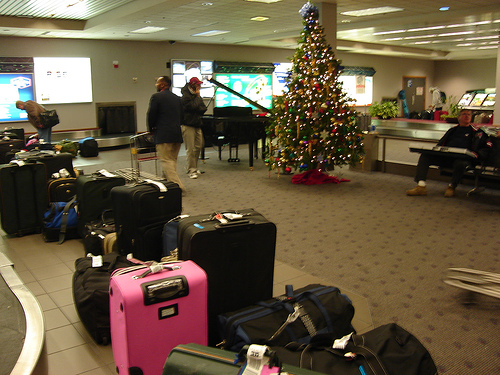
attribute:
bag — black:
[38, 107, 60, 124]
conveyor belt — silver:
[79, 124, 150, 153]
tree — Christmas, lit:
[268, 9, 363, 169]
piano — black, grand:
[197, 106, 274, 166]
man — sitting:
[410, 108, 484, 200]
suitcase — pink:
[110, 260, 211, 364]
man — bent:
[17, 100, 54, 140]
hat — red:
[83, 137, 93, 149]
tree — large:
[260, 0, 372, 181]